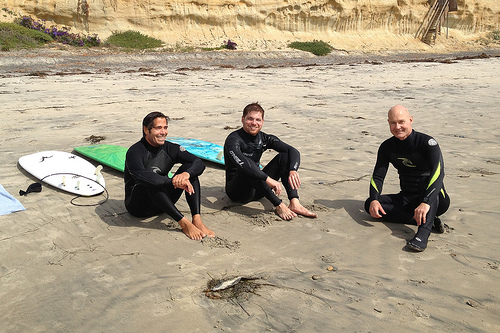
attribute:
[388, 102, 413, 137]
head — bald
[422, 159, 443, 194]
stripe — yellow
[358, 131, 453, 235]
wetsuit — black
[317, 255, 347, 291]
rock — small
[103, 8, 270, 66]
cliff — tan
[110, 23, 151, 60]
plants — green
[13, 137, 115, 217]
board — white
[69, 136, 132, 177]
surf board — green